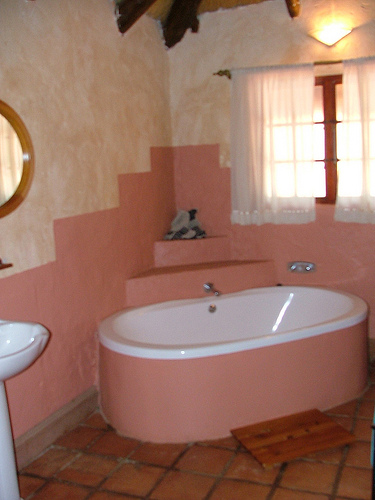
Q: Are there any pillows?
A: No, there are no pillows.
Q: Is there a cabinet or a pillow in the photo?
A: No, there are no pillows or cabinets.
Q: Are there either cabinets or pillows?
A: No, there are no pillows or cabinets.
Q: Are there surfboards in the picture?
A: No, there are no surfboards.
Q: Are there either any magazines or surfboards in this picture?
A: No, there are no surfboards or magazines.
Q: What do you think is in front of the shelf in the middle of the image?
A: The bath tub is in front of the shelf.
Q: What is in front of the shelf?
A: The bath tub is in front of the shelf.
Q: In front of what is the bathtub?
A: The bathtub is in front of the shelf.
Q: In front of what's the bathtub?
A: The bathtub is in front of the shelf.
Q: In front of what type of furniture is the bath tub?
A: The bath tub is in front of the shelf.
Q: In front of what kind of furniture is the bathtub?
A: The bath tub is in front of the shelf.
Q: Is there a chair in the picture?
A: No, there are no chairs.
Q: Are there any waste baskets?
A: No, there are no waste baskets.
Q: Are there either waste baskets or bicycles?
A: No, there are no waste baskets or bicycles.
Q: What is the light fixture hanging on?
A: The light fixture is hanging on the wall.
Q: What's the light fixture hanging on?
A: The light fixture is hanging on the wall.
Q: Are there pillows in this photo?
A: No, there are no pillows.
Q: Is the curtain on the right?
A: Yes, the curtain is on the right of the image.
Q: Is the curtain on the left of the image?
A: No, the curtain is on the right of the image.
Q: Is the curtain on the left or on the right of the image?
A: The curtain is on the right of the image.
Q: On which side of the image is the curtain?
A: The curtain is on the right of the image.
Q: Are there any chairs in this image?
A: No, there are no chairs.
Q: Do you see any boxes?
A: No, there are no boxes.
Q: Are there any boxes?
A: No, there are no boxes.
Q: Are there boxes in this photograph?
A: No, there are no boxes.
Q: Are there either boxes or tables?
A: No, there are no boxes or tables.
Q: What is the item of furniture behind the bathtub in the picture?
A: The piece of furniture is a shelf.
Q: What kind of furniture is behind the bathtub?
A: The piece of furniture is a shelf.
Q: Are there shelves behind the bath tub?
A: Yes, there is a shelf behind the bath tub.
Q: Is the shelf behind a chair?
A: No, the shelf is behind the bath tub.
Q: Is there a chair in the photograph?
A: No, there are no chairs.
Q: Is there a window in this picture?
A: Yes, there is a window.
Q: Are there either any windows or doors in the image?
A: Yes, there is a window.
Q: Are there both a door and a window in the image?
A: No, there is a window but no doors.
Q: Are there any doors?
A: No, there are no doors.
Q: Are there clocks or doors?
A: No, there are no doors or clocks.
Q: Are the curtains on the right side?
A: Yes, the curtains are on the right of the image.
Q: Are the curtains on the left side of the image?
A: No, the curtains are on the right of the image.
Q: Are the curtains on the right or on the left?
A: The curtains are on the right of the image.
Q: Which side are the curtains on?
A: The curtains are on the right of the image.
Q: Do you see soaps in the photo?
A: No, there are no soaps.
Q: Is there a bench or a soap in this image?
A: No, there are no soaps or benches.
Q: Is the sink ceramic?
A: Yes, the sink is ceramic.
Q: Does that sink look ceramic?
A: Yes, the sink is ceramic.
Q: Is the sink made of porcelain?
A: Yes, the sink is made of porcelain.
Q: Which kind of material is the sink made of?
A: The sink is made of porcelain.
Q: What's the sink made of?
A: The sink is made of porcelain.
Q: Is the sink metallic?
A: No, the sink is ceramic.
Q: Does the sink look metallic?
A: No, the sink is ceramic.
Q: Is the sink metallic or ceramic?
A: The sink is ceramic.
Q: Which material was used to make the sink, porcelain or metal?
A: The sink is made of porcelain.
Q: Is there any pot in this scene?
A: No, there are no pots.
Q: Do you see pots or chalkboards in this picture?
A: No, there are no pots or chalkboards.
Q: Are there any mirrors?
A: Yes, there is a mirror.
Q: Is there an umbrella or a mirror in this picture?
A: Yes, there is a mirror.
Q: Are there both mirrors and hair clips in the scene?
A: No, there is a mirror but no hair clips.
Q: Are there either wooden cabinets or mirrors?
A: Yes, there is a wood mirror.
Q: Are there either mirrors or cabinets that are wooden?
A: Yes, the mirror is wooden.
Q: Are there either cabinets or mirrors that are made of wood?
A: Yes, the mirror is made of wood.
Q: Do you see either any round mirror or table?
A: Yes, there is a round mirror.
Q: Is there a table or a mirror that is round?
A: Yes, the mirror is round.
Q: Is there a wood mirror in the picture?
A: Yes, there is a wood mirror.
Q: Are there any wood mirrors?
A: Yes, there is a wood mirror.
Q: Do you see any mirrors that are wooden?
A: Yes, there is a mirror that is wooden.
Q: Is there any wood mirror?
A: Yes, there is a mirror that is made of wood.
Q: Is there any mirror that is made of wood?
A: Yes, there is a mirror that is made of wood.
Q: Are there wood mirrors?
A: Yes, there is a mirror that is made of wood.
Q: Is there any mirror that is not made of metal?
A: Yes, there is a mirror that is made of wood.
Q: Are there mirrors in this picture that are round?
A: Yes, there is a round mirror.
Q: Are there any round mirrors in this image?
A: Yes, there is a round mirror.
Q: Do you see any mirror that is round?
A: Yes, there is a mirror that is round.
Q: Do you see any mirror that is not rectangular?
A: Yes, there is a round mirror.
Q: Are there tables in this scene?
A: No, there are no tables.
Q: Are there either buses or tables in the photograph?
A: No, there are no tables or buses.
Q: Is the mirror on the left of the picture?
A: Yes, the mirror is on the left of the image.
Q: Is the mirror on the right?
A: No, the mirror is on the left of the image.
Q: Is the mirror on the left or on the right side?
A: The mirror is on the left of the image.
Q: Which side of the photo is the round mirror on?
A: The mirror is on the left of the image.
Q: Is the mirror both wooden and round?
A: Yes, the mirror is wooden and round.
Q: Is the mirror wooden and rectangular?
A: No, the mirror is wooden but round.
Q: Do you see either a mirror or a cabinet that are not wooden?
A: No, there is a mirror but it is wooden.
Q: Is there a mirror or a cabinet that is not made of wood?
A: No, there is a mirror but it is made of wood.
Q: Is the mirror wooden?
A: Yes, the mirror is wooden.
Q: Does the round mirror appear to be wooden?
A: Yes, the mirror is wooden.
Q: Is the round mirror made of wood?
A: Yes, the mirror is made of wood.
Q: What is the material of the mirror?
A: The mirror is made of wood.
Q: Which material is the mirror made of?
A: The mirror is made of wood.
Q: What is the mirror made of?
A: The mirror is made of wood.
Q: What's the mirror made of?
A: The mirror is made of wood.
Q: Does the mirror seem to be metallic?
A: No, the mirror is wooden.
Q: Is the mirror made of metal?
A: No, the mirror is made of wood.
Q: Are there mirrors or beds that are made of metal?
A: No, there is a mirror but it is made of wood.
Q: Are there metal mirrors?
A: No, there is a mirror but it is made of wood.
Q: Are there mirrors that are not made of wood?
A: No, there is a mirror but it is made of wood.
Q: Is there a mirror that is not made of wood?
A: No, there is a mirror but it is made of wood.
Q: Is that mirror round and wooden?
A: Yes, the mirror is round and wooden.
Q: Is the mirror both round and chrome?
A: No, the mirror is round but wooden.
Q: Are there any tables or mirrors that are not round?
A: No, there is a mirror but it is round.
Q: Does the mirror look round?
A: Yes, the mirror is round.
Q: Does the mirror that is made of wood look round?
A: Yes, the mirror is round.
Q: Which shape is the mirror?
A: The mirror is round.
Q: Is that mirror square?
A: No, the mirror is round.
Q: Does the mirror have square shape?
A: No, the mirror is round.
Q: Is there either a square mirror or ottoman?
A: No, there is a mirror but it is round.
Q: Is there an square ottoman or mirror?
A: No, there is a mirror but it is round.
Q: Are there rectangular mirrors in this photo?
A: No, there is a mirror but it is round.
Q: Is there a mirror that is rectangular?
A: No, there is a mirror but it is round.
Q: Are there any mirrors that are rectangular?
A: No, there is a mirror but it is round.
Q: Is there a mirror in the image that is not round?
A: No, there is a mirror but it is round.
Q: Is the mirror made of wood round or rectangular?
A: The mirror is round.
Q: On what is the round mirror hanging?
A: The mirror is hanging on the wall.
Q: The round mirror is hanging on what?
A: The mirror is hanging on the wall.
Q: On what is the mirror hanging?
A: The mirror is hanging on the wall.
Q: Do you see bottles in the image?
A: No, there are no bottles.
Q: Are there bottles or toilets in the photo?
A: No, there are no bottles or toilets.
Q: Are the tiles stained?
A: Yes, the tiles are stained.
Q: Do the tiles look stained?
A: Yes, the tiles are stained.